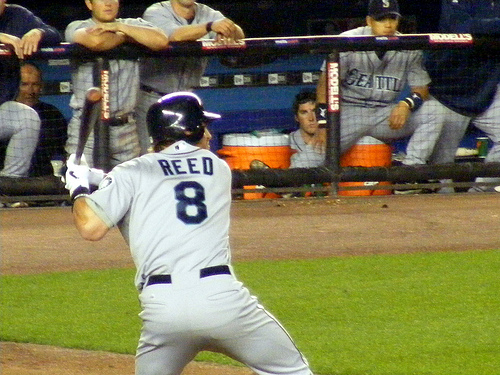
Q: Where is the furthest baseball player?
A: In the stands.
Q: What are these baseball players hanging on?
A: The rail.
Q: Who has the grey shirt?
A: Player.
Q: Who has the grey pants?
A: Player.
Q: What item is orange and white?
A: Drink dispenser.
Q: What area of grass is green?
A: Infield.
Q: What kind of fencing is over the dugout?
A: Mesh.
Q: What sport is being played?
A: Baseball.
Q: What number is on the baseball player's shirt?
A: 8.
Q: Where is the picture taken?
A: Field.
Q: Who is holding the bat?
A: A player.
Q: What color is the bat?
A: Black.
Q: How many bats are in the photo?
A: One.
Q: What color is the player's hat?
A: Blue.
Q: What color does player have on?
A: Grey and blue.